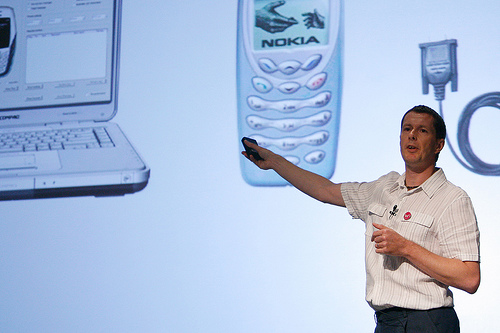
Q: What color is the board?
A: White.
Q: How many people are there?
A: One.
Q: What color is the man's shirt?
A: White and gray.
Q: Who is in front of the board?
A: The man.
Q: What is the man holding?
A: The remote.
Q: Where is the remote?
A: In the man's hand.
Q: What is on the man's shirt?
A: A microphone.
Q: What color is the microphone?
A: Black.